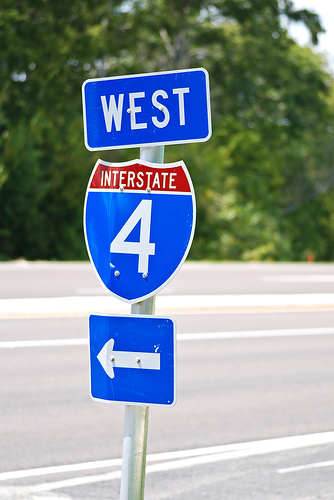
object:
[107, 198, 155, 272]
four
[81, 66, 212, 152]
blue sign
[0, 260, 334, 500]
ground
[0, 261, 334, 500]
interstate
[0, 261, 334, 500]
road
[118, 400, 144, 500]
pole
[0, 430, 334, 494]
lines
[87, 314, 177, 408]
left turn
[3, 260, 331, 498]
street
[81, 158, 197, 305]
interstate sign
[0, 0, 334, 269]
trees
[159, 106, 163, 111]
screw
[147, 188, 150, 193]
screw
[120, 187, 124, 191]
screw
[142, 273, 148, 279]
screw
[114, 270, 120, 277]
screw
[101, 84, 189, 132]
letter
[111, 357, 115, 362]
screw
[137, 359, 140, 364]
screw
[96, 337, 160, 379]
arrow